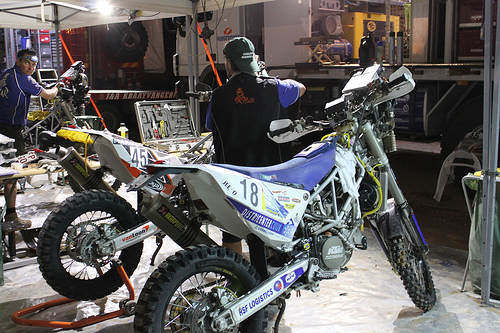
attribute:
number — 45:
[127, 143, 150, 173]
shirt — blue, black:
[203, 69, 298, 163]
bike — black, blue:
[123, 51, 442, 328]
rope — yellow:
[54, 128, 95, 168]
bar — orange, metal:
[13, 257, 146, 331]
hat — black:
[221, 34, 266, 76]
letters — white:
[237, 48, 255, 65]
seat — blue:
[222, 131, 342, 188]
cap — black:
[217, 30, 262, 83]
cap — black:
[224, 30, 267, 83]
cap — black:
[220, 35, 266, 87]